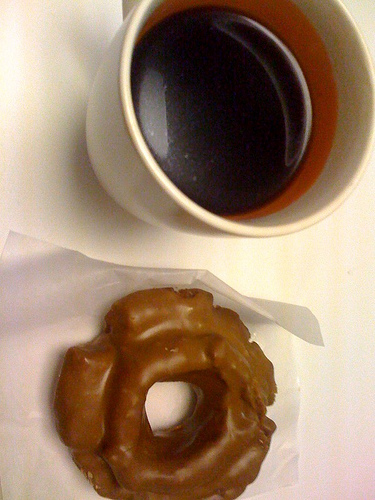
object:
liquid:
[131, 5, 315, 218]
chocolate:
[56, 284, 279, 500]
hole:
[144, 377, 201, 432]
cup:
[85, 0, 374, 241]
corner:
[241, 293, 324, 349]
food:
[51, 286, 277, 500]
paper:
[0, 228, 324, 500]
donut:
[52, 286, 278, 500]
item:
[46, 279, 278, 500]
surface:
[0, 0, 375, 500]